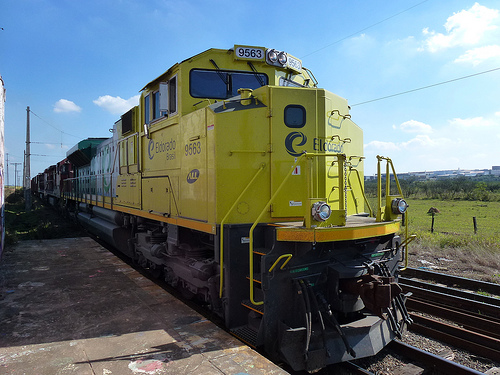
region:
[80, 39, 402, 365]
Yellow train engine on railroad tracks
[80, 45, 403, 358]
A yellow train engine number 9563 sits on tracks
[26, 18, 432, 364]
Many railroad cars sit on a railroad track.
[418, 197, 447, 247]
A tree is growing in a grass field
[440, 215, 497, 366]
A fence post in grass next to railroad tracks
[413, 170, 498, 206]
Many green trees sit in a distance on a green field of grass.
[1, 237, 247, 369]
A brown platform sits next to a a train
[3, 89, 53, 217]
Electrical tower sits in background of a blue cloudy sky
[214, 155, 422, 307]
Yellow stairs go up the front of the train engine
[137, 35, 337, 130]
Many different shapes of windows on a train engine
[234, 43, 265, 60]
9563 is this train's number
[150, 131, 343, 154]
Eldorado, noted twice, is its or its company's name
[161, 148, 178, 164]
Brasil is its location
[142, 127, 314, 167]
two fancy ribbonlike *C* shaped logos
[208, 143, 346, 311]
thin chartreuse railings lead to orange tipped stairs going up!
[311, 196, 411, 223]
two blue tinted headlights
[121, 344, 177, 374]
red+white paint splotch on the ground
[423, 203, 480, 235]
two posts in the distance, one has something mysterious on top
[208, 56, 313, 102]
one whole+one nearly whole visible train windshield wipers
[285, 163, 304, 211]
two white stickers on train front, from this distance signifying nothing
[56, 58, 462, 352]
a yellow train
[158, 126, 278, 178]
The numbers "9563" on train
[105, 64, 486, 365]
a train on the track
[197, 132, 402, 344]
yellow rail bars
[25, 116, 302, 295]
multiple train cars behind attached together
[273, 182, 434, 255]
Two lights on the front of the train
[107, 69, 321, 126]
Windows that are high on the train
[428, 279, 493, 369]
train track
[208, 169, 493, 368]
train track with train on it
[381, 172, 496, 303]
grassy land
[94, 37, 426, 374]
yellow train engine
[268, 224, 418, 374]
black cattle guard on yellow train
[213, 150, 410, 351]
ladder with yellow handrail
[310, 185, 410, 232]
round headlights on the train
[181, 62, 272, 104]
glass train windshield with windshield wipers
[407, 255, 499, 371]
train tracks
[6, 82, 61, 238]
telephone poles and power lines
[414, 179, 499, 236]
field with green grass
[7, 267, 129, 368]
concrete train platform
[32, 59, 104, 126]
blue sky with some white clouds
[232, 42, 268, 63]
the number 9563 written on a train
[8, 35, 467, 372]
a yellow colored locomotive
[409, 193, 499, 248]
a field of grass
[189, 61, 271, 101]
a windshield of a train engine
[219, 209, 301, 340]
A staircase attached to a train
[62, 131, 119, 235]
a green colored train car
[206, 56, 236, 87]
a windshield wiper on a train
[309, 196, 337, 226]
a headlight on the front of a train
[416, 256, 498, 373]
metal railroad tracks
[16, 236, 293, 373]
a train platform